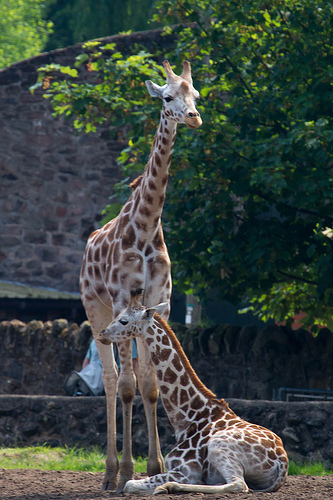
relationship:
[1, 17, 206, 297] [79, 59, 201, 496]
wall behind giraffe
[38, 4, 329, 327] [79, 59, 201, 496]
tree near giraffe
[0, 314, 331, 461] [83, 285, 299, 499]
fence behind giraffe